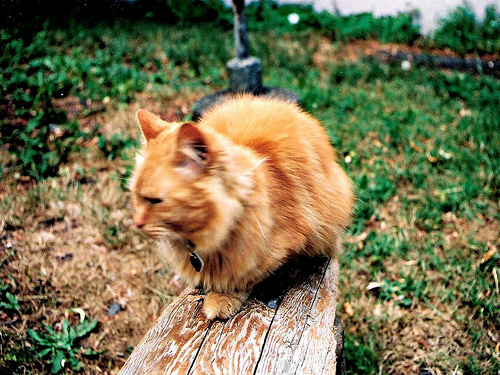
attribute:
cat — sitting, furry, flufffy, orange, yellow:
[124, 89, 367, 321]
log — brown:
[117, 255, 340, 375]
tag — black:
[189, 252, 204, 274]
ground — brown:
[1, 0, 499, 374]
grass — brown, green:
[0, 19, 499, 374]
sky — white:
[225, 2, 499, 40]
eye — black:
[144, 196, 163, 205]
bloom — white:
[288, 12, 300, 23]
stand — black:
[191, 1, 300, 122]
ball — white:
[399, 59, 411, 71]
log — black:
[359, 50, 499, 72]